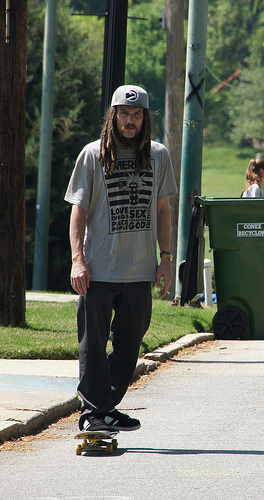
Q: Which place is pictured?
A: It is a street.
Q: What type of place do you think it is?
A: It is a street.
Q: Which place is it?
A: It is a street.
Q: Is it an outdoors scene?
A: Yes, it is outdoors.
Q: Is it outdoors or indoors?
A: It is outdoors.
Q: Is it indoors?
A: No, it is outdoors.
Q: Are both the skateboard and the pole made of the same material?
A: No, the skateboard is made of wood and the pole is made of metal.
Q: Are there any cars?
A: No, there are no cars.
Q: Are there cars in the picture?
A: No, there are no cars.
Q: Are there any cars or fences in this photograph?
A: No, there are no cars or fences.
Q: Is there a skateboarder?
A: Yes, there is a skateboarder.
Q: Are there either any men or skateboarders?
A: Yes, there is a skateboarder.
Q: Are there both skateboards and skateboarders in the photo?
A: Yes, there are both a skateboarder and a skateboard.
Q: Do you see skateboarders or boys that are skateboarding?
A: Yes, the skateboarder is skateboarding.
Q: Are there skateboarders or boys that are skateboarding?
A: Yes, the skateboarder is skateboarding.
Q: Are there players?
A: No, there are no players.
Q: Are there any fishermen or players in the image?
A: No, there are no players or fishermen.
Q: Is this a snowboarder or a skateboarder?
A: This is a skateboarder.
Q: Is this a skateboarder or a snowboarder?
A: This is a skateboarder.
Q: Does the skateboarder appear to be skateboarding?
A: Yes, the skateboarder is skateboarding.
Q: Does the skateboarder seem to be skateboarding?
A: Yes, the skateboarder is skateboarding.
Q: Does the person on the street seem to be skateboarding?
A: Yes, the skateboarder is skateboarding.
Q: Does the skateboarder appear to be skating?
A: No, the skateboarder is skateboarding.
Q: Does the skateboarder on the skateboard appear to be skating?
A: No, the skateboarder is skateboarding.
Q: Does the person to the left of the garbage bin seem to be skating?
A: No, the skateboarder is skateboarding.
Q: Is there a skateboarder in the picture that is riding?
A: No, there is a skateboarder but he is skateboarding.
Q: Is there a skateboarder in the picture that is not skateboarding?
A: No, there is a skateboarder but he is skateboarding.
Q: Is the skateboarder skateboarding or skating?
A: The skateboarder is skateboarding.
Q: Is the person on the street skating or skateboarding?
A: The skateboarder is skateboarding.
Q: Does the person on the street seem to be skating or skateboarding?
A: The skateboarder is skateboarding.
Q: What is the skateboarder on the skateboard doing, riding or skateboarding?
A: The skateboarder is skateboarding.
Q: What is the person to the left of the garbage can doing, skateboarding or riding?
A: The skateboarder is skateboarding.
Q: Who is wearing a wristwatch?
A: The skateboarder is wearing a wristwatch.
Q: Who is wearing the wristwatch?
A: The skateboarder is wearing a wristwatch.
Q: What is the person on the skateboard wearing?
A: The skateboarder is wearing a wristwatch.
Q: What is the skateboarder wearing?
A: The skateboarder is wearing a wristwatch.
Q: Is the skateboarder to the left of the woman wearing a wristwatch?
A: Yes, the skateboarder is wearing a wristwatch.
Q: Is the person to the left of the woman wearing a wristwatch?
A: Yes, the skateboarder is wearing a wristwatch.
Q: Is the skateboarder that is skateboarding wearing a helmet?
A: No, the skateboarder is wearing a wristwatch.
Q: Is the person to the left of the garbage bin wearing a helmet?
A: No, the skateboarder is wearing a wristwatch.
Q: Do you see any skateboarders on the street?
A: Yes, there is a skateboarder on the street.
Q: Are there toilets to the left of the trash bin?
A: No, there is a skateboarder to the left of the trash bin.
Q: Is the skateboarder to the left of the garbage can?
A: Yes, the skateboarder is to the left of the garbage can.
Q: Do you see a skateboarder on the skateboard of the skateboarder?
A: Yes, there is a skateboarder on the skateboard.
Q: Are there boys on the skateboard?
A: No, there is a skateboarder on the skateboard.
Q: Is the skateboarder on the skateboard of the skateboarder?
A: Yes, the skateboarder is on the skateboard.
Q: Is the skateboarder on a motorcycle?
A: No, the skateboarder is on the skateboard.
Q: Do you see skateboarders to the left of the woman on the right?
A: Yes, there is a skateboarder to the left of the woman.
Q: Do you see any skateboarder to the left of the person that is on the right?
A: Yes, there is a skateboarder to the left of the woman.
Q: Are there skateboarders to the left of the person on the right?
A: Yes, there is a skateboarder to the left of the woman.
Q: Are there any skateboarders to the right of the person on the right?
A: No, the skateboarder is to the left of the woman.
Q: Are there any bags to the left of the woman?
A: No, there is a skateboarder to the left of the woman.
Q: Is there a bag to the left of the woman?
A: No, there is a skateboarder to the left of the woman.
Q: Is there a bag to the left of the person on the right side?
A: No, there is a skateboarder to the left of the woman.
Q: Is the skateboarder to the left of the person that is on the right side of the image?
A: Yes, the skateboarder is to the left of the woman.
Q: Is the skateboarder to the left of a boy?
A: No, the skateboarder is to the left of the woman.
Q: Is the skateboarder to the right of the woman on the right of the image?
A: No, the skateboarder is to the left of the woman.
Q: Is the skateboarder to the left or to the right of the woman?
A: The skateboarder is to the left of the woman.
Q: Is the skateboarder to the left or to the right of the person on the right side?
A: The skateboarder is to the left of the woman.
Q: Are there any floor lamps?
A: No, there are no floor lamps.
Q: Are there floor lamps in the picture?
A: No, there are no floor lamps.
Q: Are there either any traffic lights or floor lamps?
A: No, there are no floor lamps or traffic lights.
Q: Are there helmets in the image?
A: No, there are no helmets.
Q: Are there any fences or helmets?
A: No, there are no helmets or fences.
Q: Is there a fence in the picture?
A: No, there are no fences.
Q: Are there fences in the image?
A: No, there are no fences.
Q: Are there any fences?
A: No, there are no fences.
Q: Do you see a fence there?
A: No, there are no fences.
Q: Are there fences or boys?
A: No, there are no fences or boys.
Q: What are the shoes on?
A: The shoes are on the skateboard.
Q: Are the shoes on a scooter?
A: No, the shoes are on a skateboard.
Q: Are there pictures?
A: No, there are no pictures.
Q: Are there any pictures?
A: No, there are no pictures.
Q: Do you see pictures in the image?
A: No, there are no pictures.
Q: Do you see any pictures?
A: No, there are no pictures.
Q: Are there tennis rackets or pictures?
A: No, there are no pictures or tennis rackets.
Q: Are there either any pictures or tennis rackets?
A: No, there are no pictures or tennis rackets.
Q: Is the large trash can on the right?
A: Yes, the garbage can is on the right of the image.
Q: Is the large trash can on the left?
A: No, the trashcan is on the right of the image.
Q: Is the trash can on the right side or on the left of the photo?
A: The trash can is on the right of the image.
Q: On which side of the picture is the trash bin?
A: The trash bin is on the right of the image.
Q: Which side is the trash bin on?
A: The trash bin is on the right of the image.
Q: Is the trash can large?
A: Yes, the trash can is large.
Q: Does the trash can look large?
A: Yes, the trash can is large.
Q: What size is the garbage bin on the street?
A: The garbage can is large.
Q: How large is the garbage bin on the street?
A: The trashcan is large.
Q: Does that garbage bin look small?
A: No, the garbage bin is large.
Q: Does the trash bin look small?
A: No, the trash bin is large.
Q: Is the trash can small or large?
A: The trash can is large.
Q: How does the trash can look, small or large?
A: The trash can is large.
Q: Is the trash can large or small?
A: The trash can is large.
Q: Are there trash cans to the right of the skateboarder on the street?
A: Yes, there is a trash can to the right of the skateboarder.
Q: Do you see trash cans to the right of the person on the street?
A: Yes, there is a trash can to the right of the skateboarder.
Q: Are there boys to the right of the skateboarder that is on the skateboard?
A: No, there is a trash can to the right of the skateboarder.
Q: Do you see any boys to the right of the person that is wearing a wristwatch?
A: No, there is a trash can to the right of the skateboarder.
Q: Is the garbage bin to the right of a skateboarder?
A: Yes, the garbage bin is to the right of a skateboarder.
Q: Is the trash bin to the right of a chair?
A: No, the trash bin is to the right of a skateboarder.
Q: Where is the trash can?
A: The trash can is on the street.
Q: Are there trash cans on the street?
A: Yes, there is a trash can on the street.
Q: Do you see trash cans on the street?
A: Yes, there is a trash can on the street.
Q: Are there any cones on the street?
A: No, there is a trash can on the street.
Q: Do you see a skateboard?
A: Yes, there is a skateboard.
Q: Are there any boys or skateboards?
A: Yes, there is a skateboard.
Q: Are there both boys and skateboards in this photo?
A: No, there is a skateboard but no boys.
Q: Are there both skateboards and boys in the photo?
A: No, there is a skateboard but no boys.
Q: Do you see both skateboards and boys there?
A: No, there is a skateboard but no boys.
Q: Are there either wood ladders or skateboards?
A: Yes, there is a wood skateboard.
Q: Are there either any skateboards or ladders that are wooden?
A: Yes, the skateboard is wooden.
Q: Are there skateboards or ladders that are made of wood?
A: Yes, the skateboard is made of wood.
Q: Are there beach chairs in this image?
A: No, there are no beach chairs.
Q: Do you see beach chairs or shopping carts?
A: No, there are no beach chairs or shopping carts.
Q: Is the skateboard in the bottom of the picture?
A: Yes, the skateboard is in the bottom of the image.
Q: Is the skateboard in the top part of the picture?
A: No, the skateboard is in the bottom of the image.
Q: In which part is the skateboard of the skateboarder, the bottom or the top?
A: The skateboard is in the bottom of the image.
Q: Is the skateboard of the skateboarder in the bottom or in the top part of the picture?
A: The skateboard is in the bottom of the image.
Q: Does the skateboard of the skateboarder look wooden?
A: Yes, the skateboard is wooden.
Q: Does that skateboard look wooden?
A: Yes, the skateboard is wooden.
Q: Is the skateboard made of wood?
A: Yes, the skateboard is made of wood.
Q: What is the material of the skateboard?
A: The skateboard is made of wood.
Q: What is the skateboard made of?
A: The skateboard is made of wood.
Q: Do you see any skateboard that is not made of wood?
A: No, there is a skateboard but it is made of wood.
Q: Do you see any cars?
A: No, there are no cars.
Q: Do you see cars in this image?
A: No, there are no cars.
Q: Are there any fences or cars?
A: No, there are no cars or fences.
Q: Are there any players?
A: No, there are no players.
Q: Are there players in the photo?
A: No, there are no players.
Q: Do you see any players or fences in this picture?
A: No, there are no players or fences.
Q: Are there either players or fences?
A: No, there are no players or fences.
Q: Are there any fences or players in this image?
A: No, there are no players or fences.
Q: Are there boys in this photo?
A: No, there are no boys.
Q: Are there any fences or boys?
A: No, there are no boys or fences.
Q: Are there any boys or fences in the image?
A: No, there are no boys or fences.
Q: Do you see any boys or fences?
A: No, there are no boys or fences.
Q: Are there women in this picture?
A: Yes, there is a woman.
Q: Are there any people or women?
A: Yes, there is a woman.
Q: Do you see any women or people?
A: Yes, there is a woman.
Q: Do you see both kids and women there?
A: No, there is a woman but no children.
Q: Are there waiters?
A: No, there are no waiters.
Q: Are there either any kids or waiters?
A: No, there are no waiters or kids.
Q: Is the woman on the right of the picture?
A: Yes, the woman is on the right of the image.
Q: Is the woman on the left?
A: No, the woman is on the right of the image.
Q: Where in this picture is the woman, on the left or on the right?
A: The woman is on the right of the image.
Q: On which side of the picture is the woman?
A: The woman is on the right of the image.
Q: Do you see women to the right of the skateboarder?
A: Yes, there is a woman to the right of the skateboarder.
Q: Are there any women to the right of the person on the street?
A: Yes, there is a woman to the right of the skateboarder.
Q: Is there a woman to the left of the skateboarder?
A: No, the woman is to the right of the skateboarder.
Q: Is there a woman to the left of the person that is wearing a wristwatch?
A: No, the woman is to the right of the skateboarder.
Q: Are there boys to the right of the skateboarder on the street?
A: No, there is a woman to the right of the skateboarder.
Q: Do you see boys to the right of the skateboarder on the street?
A: No, there is a woman to the right of the skateboarder.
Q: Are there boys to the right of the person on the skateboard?
A: No, there is a woman to the right of the skateboarder.